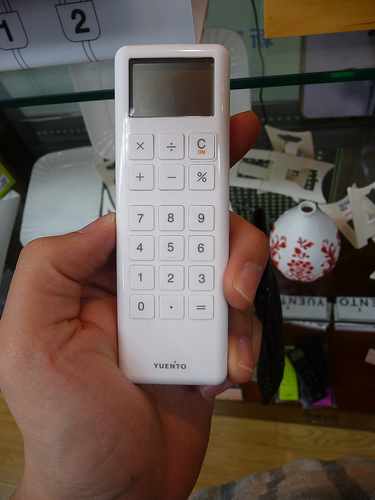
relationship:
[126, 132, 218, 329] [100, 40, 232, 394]
buttons on calculator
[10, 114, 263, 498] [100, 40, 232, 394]
hand holding calculator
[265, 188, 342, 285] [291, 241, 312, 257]
vase has red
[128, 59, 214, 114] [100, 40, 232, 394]
screen of calculator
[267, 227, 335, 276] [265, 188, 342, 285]
print on vase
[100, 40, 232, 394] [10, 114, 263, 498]
calculator in hand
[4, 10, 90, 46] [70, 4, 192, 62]
numbers on paper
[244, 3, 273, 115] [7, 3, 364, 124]
cord on wall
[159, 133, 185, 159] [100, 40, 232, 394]
button on calculator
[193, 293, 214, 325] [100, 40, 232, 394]
equal on calculator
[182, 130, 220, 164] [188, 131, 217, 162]
button for button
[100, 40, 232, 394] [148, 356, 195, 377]
calculator has yuento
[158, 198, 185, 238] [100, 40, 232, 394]
button on calculator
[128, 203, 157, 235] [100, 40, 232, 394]
button on calculator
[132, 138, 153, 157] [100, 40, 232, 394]
button on calculator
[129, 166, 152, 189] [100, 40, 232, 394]
button on calculator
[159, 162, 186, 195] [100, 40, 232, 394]
button on calculator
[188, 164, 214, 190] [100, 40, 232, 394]
button on calculator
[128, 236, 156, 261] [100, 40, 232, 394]
button on calculator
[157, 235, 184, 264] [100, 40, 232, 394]
button on calculator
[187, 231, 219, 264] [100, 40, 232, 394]
button on calculator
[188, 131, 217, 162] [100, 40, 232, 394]
button button of calculator